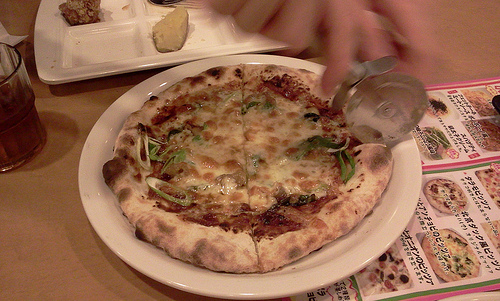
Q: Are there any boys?
A: No, there are no boys.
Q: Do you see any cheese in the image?
A: Yes, there is cheese.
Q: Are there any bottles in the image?
A: No, there are no bottles.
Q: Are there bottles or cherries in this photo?
A: No, there are no bottles or cherries.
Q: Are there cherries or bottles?
A: No, there are no bottles or cherries.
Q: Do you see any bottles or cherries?
A: No, there are no bottles or cherries.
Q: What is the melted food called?
A: The food is cheese.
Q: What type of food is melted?
A: The food is cheese.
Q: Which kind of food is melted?
A: The food is cheese.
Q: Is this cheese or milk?
A: This is cheese.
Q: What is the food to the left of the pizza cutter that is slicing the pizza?
A: The food is cheese.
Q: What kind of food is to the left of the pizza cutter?
A: The food is cheese.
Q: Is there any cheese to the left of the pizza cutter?
A: Yes, there is cheese to the left of the pizza cutter.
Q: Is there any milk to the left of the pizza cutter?
A: No, there is cheese to the left of the pizza cutter.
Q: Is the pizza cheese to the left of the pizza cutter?
A: Yes, the cheese is to the left of the pizza cutter.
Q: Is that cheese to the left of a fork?
A: No, the cheese is to the left of the pizza cutter.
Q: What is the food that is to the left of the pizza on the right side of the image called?
A: The food is cheese.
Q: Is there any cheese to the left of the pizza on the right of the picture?
A: Yes, there is cheese to the left of the pizza.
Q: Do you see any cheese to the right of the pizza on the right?
A: No, the cheese is to the left of the pizza.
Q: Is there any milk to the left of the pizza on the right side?
A: No, there is cheese to the left of the pizza.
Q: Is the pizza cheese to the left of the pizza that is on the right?
A: Yes, the cheese is to the left of the pizza.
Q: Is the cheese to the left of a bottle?
A: No, the cheese is to the left of the pizza.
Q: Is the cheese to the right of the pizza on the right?
A: No, the cheese is to the left of the pizza.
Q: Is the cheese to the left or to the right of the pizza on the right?
A: The cheese is to the left of the pizza.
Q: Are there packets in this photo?
A: No, there are no packets.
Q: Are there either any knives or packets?
A: No, there are no packets or knives.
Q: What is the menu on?
A: The menu is on the table.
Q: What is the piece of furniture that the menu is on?
A: The piece of furniture is a table.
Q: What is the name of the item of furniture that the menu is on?
A: The piece of furniture is a table.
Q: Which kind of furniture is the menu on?
A: The menu is on the table.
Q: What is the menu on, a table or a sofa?
A: The menu is on a table.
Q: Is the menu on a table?
A: Yes, the menu is on a table.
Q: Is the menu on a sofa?
A: No, the menu is on a table.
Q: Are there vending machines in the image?
A: No, there are no vending machines.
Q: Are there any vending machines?
A: No, there are no vending machines.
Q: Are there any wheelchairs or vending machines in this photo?
A: No, there are no vending machines or wheelchairs.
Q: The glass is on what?
A: The glass is on the table.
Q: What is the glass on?
A: The glass is on the table.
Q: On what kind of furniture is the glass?
A: The glass is on the table.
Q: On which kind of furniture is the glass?
A: The glass is on the table.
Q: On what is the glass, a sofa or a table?
A: The glass is on a table.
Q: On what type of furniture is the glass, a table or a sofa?
A: The glass is on a table.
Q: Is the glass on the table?
A: Yes, the glass is on the table.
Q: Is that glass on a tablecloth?
A: No, the glass is on the table.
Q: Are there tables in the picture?
A: Yes, there is a table.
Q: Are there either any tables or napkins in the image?
A: Yes, there is a table.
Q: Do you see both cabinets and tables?
A: No, there is a table but no cabinets.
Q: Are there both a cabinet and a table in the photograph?
A: No, there is a table but no cabinets.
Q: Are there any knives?
A: No, there are no knives.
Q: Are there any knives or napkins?
A: No, there are no knives or napkins.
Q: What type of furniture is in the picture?
A: The furniture is a table.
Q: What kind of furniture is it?
A: The piece of furniture is a table.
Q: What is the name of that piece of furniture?
A: That is a table.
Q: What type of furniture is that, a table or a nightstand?
A: That is a table.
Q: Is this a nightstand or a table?
A: This is a table.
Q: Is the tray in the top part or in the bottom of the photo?
A: The tray is in the top of the image.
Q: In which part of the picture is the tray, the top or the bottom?
A: The tray is in the top of the image.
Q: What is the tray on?
A: The tray is on the table.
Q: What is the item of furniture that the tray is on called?
A: The piece of furniture is a table.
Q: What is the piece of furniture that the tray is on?
A: The piece of furniture is a table.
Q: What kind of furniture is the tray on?
A: The tray is on the table.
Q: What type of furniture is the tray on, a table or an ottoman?
A: The tray is on a table.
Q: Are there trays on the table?
A: Yes, there is a tray on the table.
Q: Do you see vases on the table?
A: No, there is a tray on the table.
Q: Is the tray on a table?
A: Yes, the tray is on a table.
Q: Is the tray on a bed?
A: No, the tray is on a table.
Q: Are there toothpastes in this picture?
A: No, there are no toothpastes.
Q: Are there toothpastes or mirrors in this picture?
A: No, there are no toothpastes or mirrors.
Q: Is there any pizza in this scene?
A: Yes, there is a pizza.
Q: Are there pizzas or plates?
A: Yes, there is a pizza.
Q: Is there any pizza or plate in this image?
A: Yes, there is a pizza.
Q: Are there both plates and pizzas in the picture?
A: Yes, there are both a pizza and a plate.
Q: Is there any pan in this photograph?
A: No, there are no pans.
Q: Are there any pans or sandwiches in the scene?
A: No, there are no pans or sandwiches.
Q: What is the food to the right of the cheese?
A: The food is a pizza.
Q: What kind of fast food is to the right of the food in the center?
A: The food is a pizza.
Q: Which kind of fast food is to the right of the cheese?
A: The food is a pizza.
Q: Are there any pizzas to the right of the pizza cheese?
A: Yes, there is a pizza to the right of the cheese.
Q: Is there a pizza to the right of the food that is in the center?
A: Yes, there is a pizza to the right of the cheese.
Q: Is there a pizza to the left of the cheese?
A: No, the pizza is to the right of the cheese.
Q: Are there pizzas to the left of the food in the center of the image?
A: No, the pizza is to the right of the cheese.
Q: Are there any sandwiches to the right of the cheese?
A: No, there is a pizza to the right of the cheese.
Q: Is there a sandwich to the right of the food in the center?
A: No, there is a pizza to the right of the cheese.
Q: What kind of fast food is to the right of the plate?
A: The food is a pizza.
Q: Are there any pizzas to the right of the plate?
A: Yes, there is a pizza to the right of the plate.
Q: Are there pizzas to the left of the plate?
A: No, the pizza is to the right of the plate.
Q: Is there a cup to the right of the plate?
A: No, there is a pizza to the right of the plate.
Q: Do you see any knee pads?
A: No, there are no knee pads.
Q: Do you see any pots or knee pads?
A: No, there are no knee pads or pots.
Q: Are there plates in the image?
A: Yes, there is a plate.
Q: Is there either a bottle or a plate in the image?
A: Yes, there is a plate.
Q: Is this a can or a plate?
A: This is a plate.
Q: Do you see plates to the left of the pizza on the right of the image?
A: Yes, there is a plate to the left of the pizza.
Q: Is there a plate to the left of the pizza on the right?
A: Yes, there is a plate to the left of the pizza.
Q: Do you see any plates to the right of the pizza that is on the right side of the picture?
A: No, the plate is to the left of the pizza.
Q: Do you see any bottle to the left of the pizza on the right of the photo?
A: No, there is a plate to the left of the pizza.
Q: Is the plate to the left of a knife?
A: No, the plate is to the left of a pizza.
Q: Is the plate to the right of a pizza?
A: No, the plate is to the left of a pizza.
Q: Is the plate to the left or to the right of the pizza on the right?
A: The plate is to the left of the pizza.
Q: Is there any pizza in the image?
A: Yes, there is a pizza.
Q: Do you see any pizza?
A: Yes, there is a pizza.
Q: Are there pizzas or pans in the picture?
A: Yes, there is a pizza.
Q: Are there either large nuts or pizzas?
A: Yes, there is a large pizza.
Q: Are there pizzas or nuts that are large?
A: Yes, the pizza is large.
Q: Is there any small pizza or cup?
A: Yes, there is a small pizza.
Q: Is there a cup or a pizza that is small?
A: Yes, the pizza is small.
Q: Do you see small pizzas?
A: Yes, there is a small pizza.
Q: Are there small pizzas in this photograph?
A: Yes, there is a small pizza.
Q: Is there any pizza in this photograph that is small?
A: Yes, there is a pizza that is small.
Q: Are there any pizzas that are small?
A: Yes, there is a pizza that is small.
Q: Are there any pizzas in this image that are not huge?
A: Yes, there is a small pizza.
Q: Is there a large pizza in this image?
A: Yes, there is a large pizza.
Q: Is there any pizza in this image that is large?
A: Yes, there is a pizza that is large.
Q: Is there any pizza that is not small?
A: Yes, there is a large pizza.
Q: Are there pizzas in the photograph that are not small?
A: Yes, there is a large pizza.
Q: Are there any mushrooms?
A: No, there are no mushrooms.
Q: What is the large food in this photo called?
A: The food is a pizza.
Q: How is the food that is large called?
A: The food is a pizza.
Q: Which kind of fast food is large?
A: The fast food is a pizza.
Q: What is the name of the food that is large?
A: The food is a pizza.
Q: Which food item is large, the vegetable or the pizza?
A: The pizza is large.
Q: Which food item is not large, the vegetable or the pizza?
A: The vegetable is not large.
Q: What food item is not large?
A: The food item is a vegetable.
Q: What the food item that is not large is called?
A: The food item is a vegetable.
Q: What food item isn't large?
A: The food item is a vegetable.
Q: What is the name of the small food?
A: The food is a pizza.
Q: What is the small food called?
A: The food is a pizza.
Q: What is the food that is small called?
A: The food is a pizza.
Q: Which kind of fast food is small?
A: The fast food is a pizza.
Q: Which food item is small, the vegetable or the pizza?
A: The pizza is small.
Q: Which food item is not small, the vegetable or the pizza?
A: The vegetable is not small.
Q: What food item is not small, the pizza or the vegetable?
A: The vegetable is not small.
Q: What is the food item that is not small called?
A: The food item is a vegetable.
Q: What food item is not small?
A: The food item is a vegetable.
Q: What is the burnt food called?
A: The food is a pizza.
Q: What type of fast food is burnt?
A: The fast food is a pizza.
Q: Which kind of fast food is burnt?
A: The fast food is a pizza.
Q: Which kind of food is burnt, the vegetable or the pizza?
A: The pizza is burnt.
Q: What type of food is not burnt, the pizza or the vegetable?
A: The vegetable is not burnt.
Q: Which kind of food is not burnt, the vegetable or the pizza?
A: The vegetable is not burnt.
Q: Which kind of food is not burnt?
A: The food is a vegetable.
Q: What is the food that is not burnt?
A: The food is a vegetable.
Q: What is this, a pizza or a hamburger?
A: This is a pizza.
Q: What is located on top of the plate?
A: The pizza is on top of the plate.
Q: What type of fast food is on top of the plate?
A: The food is a pizza.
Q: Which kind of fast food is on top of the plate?
A: The food is a pizza.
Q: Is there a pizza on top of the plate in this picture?
A: Yes, there is a pizza on top of the plate.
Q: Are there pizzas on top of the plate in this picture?
A: Yes, there is a pizza on top of the plate.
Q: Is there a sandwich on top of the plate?
A: No, there is a pizza on top of the plate.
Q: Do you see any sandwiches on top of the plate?
A: No, there is a pizza on top of the plate.